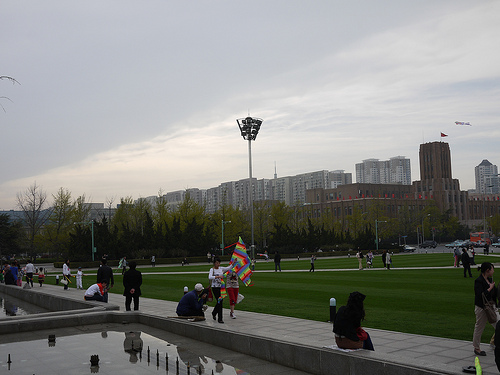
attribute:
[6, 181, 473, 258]
trees — several, row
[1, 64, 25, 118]
branches — leaveless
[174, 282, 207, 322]
man — sitting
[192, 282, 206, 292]
hat — white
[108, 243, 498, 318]
green-grassy field — green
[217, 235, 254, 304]
kite — multicolored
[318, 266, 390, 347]
person — seated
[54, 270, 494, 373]
sidewalk — concrete